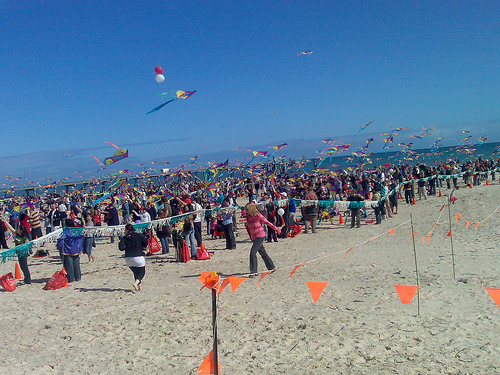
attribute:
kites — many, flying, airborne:
[0, 122, 495, 174]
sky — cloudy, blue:
[3, 1, 495, 142]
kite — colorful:
[145, 88, 195, 113]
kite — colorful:
[101, 149, 129, 167]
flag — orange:
[198, 209, 497, 312]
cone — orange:
[410, 182, 491, 203]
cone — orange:
[12, 262, 23, 280]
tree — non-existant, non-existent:
[2, 1, 499, 374]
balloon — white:
[155, 73, 164, 83]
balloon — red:
[155, 65, 164, 74]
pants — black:
[129, 266, 145, 282]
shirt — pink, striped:
[246, 211, 278, 238]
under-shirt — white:
[124, 255, 146, 266]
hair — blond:
[246, 201, 260, 215]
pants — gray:
[249, 239, 275, 274]